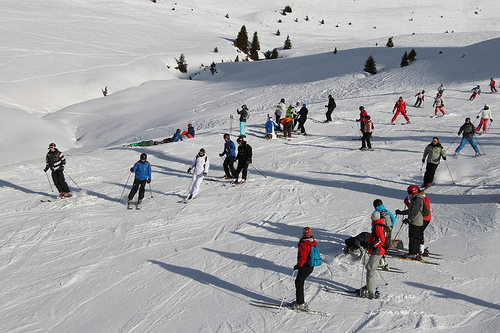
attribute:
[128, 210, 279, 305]
snow — white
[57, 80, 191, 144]
valley — small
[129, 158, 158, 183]
jacket — blue 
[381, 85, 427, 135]
snowsuit — winter, all red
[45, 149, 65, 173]
coat — black 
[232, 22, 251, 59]
tree — green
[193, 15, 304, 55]
trees — sparse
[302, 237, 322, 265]
backpack — blue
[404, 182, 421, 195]
helmet — red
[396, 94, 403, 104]
hat — black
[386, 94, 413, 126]
ski suit — red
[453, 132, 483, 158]
snowpants — dark turquoise